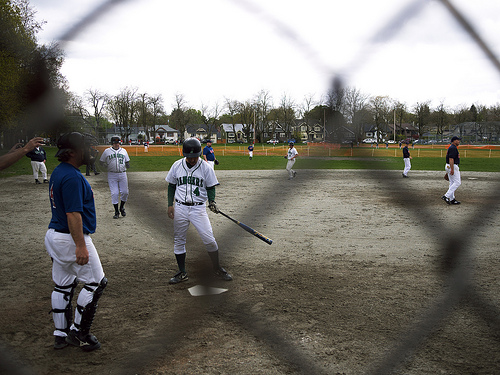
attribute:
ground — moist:
[253, 256, 453, 342]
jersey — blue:
[44, 162, 96, 232]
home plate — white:
[186, 280, 227, 300]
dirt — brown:
[324, 195, 389, 285]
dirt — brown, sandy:
[283, 228, 380, 277]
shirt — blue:
[47, 164, 99, 234]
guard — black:
[72, 278, 106, 332]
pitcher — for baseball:
[432, 132, 469, 214]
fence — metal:
[121, 143, 497, 161]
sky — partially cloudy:
[33, 3, 494, 106]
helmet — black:
[180, 134, 205, 162]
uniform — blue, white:
[163, 159, 226, 270]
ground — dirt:
[0, 170, 495, 372]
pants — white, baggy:
[44, 226, 106, 338]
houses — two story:
[255, 123, 313, 142]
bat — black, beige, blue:
[219, 206, 275, 248]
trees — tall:
[218, 85, 368, 145]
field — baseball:
[253, 160, 408, 302]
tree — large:
[5, 37, 123, 178]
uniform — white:
[160, 158, 219, 262]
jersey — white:
[164, 159, 216, 256]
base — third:
[107, 205, 124, 217]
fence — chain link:
[16, 10, 242, 350]